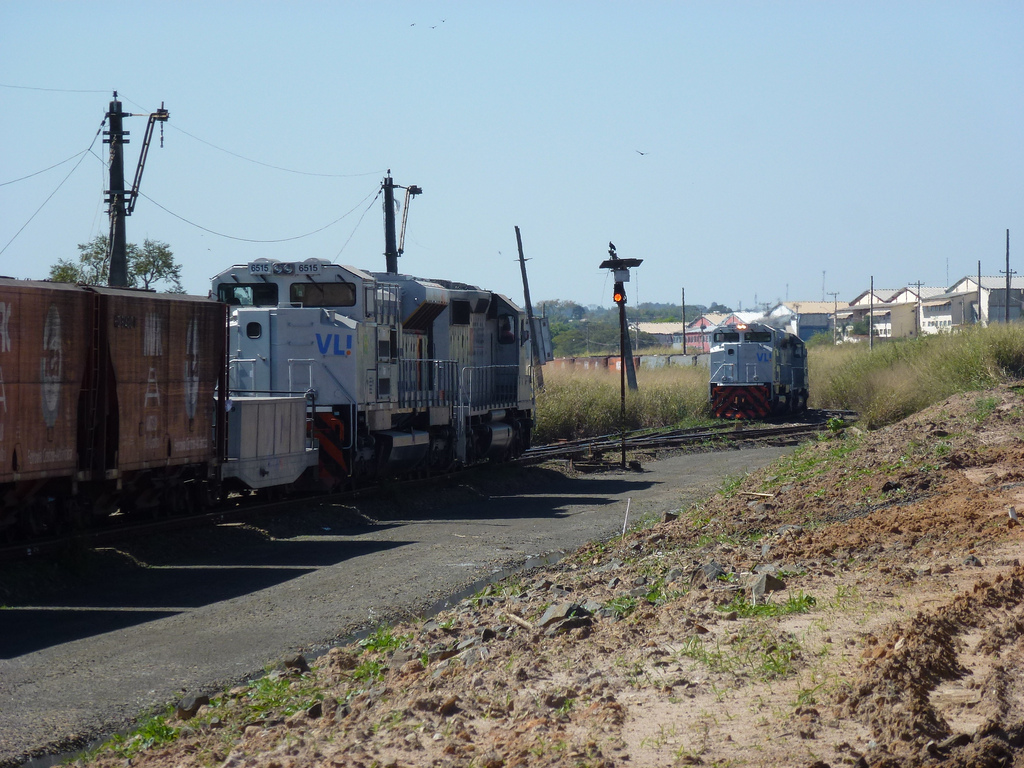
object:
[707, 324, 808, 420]
train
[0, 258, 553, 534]
train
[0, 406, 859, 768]
track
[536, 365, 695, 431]
grass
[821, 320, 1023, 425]
grass